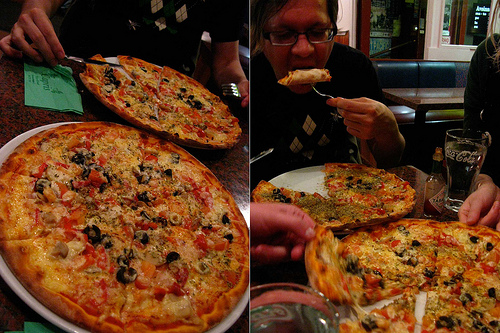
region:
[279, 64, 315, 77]
man eating pizza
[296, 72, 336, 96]
pizza is on a fork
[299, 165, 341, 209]
slice missing from pizza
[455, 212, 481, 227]
person taking a slice of pizza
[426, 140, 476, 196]
CocaCola glass on the table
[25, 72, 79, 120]
green napkin next to pizza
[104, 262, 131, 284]
black olives on the pizza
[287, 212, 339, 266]
person picking up slice of pizza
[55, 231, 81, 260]
sausage on the pizza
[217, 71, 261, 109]
person's hand is holding a cellphone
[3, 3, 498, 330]
Two photos on each side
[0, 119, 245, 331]
A pizza in the foreground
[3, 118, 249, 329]
Pizza is on a white plate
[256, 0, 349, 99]
Person is eating pizza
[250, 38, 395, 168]
Person is wearing a shirt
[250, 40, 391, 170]
The shirt is black in color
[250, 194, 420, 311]
Person grabbing a slice of pizza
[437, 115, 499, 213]
Person is holding a glass cup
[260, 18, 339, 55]
Person is wearing eyeglasses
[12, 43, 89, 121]
A green colored napkin on the table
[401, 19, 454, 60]
large white door in the back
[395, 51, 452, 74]
blue edge of seating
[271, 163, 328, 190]
portion of white plate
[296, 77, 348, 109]
fork in woman's hand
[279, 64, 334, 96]
food at edge of fork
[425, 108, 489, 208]
large clear drinking glass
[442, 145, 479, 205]
dark liquid in drinking glass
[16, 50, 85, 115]
green envelope on surface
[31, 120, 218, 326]
large pizza pie on white plate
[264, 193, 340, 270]
fingers on slice of pizza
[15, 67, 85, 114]
A sheet of paper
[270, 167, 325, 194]
A white plate in the photo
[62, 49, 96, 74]
A knife in the photo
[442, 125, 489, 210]
A glass in the photo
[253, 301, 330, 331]
Water in the glass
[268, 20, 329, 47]
Eyeglasses in the photo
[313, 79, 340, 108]
A fork in the photo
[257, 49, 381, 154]
A black and white sweater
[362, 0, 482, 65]
A window in the background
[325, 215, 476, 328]
A pizza cut in slices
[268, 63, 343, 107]
Pizza with cheese held by a fork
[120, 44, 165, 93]
Small slice of pizza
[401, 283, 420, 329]
Small slice of pizza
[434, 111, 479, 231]
Glass cup with drink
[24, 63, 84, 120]
Green colored napkin on table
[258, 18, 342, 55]
Black framed glasses on face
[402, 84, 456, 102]
reflection on a table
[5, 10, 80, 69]
A hand on someone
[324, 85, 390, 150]
A hand on someone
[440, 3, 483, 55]
A mirror on the wall